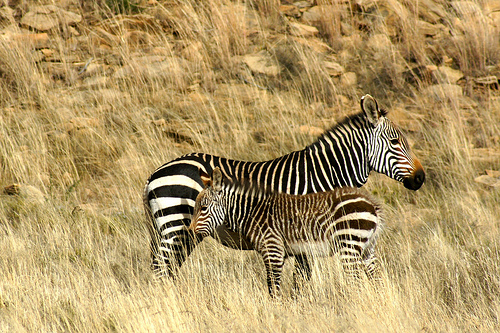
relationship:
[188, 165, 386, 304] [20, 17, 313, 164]
animal in field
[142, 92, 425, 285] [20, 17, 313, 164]
adult zebra in field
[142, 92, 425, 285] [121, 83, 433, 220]
adult zebra beside zebra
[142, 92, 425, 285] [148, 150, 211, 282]
adult zebra has stripes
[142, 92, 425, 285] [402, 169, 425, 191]
adult zebra has mouth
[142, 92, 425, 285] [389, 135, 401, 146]
adult zebra has eye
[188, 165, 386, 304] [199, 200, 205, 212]
animal has eye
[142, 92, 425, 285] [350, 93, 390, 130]
adult zebra has ear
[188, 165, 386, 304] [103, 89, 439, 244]
animal next to adult zebra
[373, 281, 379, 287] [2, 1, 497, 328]
tip of grass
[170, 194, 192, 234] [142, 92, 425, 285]
shadow on adult zebra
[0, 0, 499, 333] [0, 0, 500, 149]
field in background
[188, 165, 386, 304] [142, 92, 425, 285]
animal with adult zebra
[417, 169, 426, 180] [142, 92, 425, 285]
nose of adult zebra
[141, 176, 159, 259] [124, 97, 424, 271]
tail of zebra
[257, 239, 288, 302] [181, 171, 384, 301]
front leg of zebra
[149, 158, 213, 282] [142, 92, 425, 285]
leg of adult zebra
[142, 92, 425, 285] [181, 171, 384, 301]
adult zebra with zebra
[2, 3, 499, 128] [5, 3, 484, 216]
rocks across slope